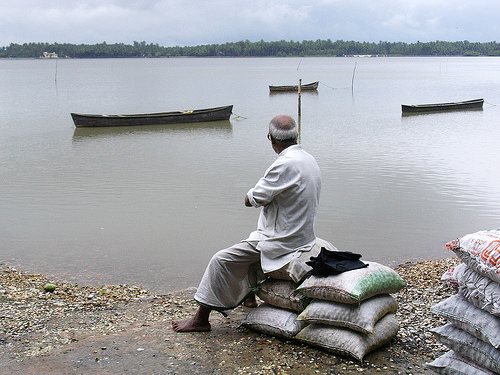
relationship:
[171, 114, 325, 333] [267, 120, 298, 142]
man has hair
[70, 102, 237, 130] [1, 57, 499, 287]
boat in lake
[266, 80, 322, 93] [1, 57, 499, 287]
boat in lake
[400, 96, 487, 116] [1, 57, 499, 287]
boat in lake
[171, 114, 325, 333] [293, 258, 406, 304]
man sitting on sack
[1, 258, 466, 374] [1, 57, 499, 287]
beach meets lake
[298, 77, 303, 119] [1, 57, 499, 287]
docking pole in lake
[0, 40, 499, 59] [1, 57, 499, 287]
trees along lake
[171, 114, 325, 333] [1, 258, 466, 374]
man on beach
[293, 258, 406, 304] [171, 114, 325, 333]
sack under man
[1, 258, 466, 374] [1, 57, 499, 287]
beach by lake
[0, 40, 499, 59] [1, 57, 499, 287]
trees by lake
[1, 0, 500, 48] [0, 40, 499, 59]
sky behind trees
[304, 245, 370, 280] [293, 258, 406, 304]
item on sack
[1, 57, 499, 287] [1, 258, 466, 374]
lake meets beach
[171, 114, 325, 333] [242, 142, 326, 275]
man wearing white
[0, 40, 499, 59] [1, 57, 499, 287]
trees behind lake